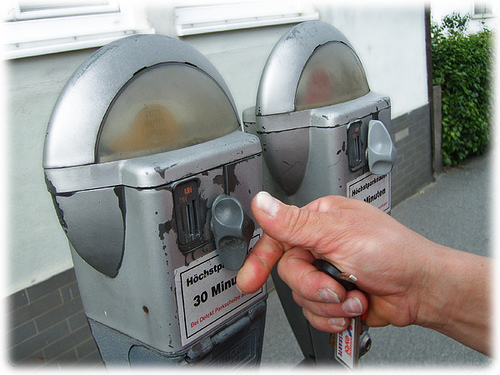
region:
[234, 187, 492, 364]
right hand holding rental car keys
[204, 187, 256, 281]
knob on a parking meter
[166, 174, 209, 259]
coin slot on a parking meter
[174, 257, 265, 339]
parking meter instructions in German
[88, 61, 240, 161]
parking meter window with yellow flag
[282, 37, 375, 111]
parking meter window with red flag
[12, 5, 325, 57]
white window sills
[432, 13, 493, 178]
green shrubbery next to a sidewalk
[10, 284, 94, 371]
brick pattern on wall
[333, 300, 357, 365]
plastic rental car keytag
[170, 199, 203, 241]
three slots on parking meter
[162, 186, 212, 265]
three slots for coins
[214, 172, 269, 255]
dial to turn on parking meter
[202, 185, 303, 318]
person going to turn the dial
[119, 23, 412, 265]
two parking meters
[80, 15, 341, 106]
parking meters are on the sidewalk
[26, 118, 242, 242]
parking meter is missing paint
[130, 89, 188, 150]
tells you how much time you have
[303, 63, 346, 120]
sign is red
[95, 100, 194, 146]
sign is yellow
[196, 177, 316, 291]
Someone about to turn parking meter.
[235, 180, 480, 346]
Someone holding keys in their hand.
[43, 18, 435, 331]
Two silver parking meters outside.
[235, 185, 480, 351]
White/caucasion hand holding keys.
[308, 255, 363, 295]
Black car key in man's hand.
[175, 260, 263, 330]
30 minute parking sign on meter.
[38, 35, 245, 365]
Chipped paint on the parking meter.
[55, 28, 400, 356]
White tag hanging from keys.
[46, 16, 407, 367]
White sign with black letters.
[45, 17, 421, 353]
Meters outside of a building.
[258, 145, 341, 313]
a hand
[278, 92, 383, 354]
a hand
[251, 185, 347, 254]
thumb of a person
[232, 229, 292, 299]
finger of a person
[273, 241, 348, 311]
finger of a person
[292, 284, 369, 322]
finger of a person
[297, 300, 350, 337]
finger of a person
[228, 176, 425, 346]
hand of a person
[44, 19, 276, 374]
silver metal parking meter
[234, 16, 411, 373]
silver metal parking meter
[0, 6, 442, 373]
building painted white with brick foundation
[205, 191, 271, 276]
lever of parking meter